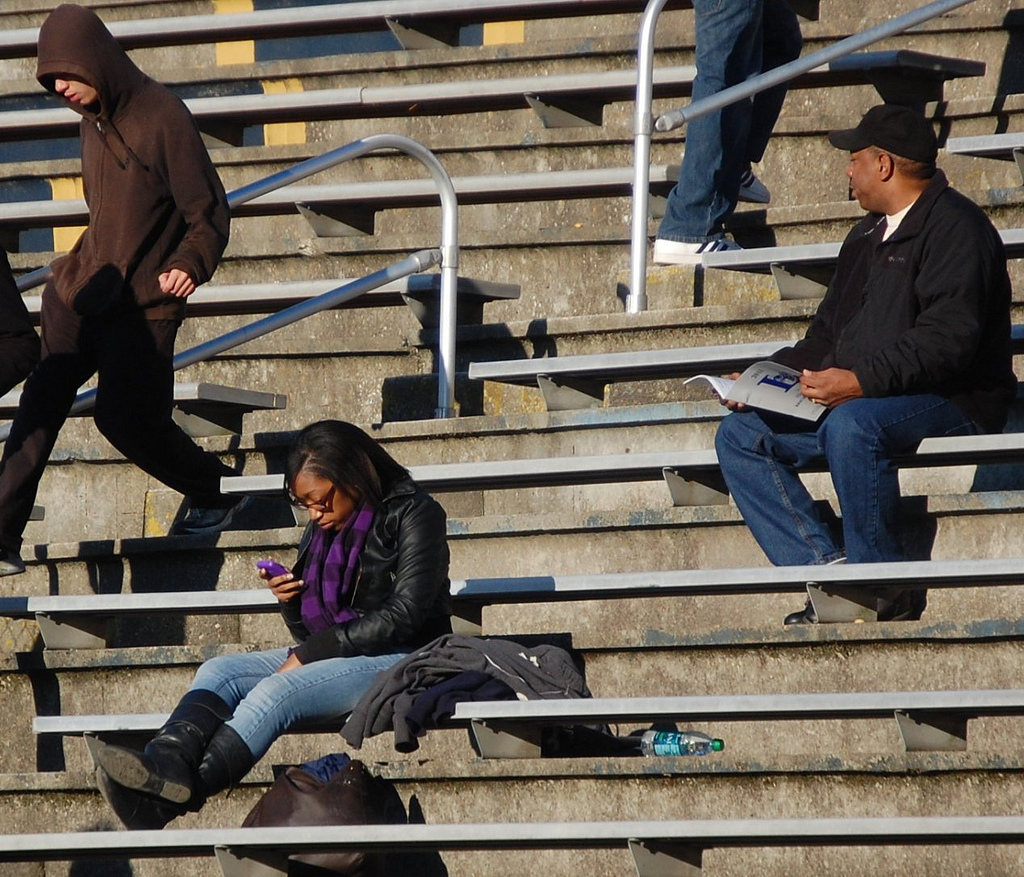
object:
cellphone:
[255, 559, 298, 586]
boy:
[715, 103, 1014, 618]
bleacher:
[726, 696, 800, 753]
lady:
[85, 418, 454, 813]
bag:
[235, 752, 422, 877]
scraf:
[296, 510, 372, 637]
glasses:
[290, 483, 337, 510]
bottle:
[641, 730, 726, 757]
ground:
[611, 649, 649, 698]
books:
[681, 359, 832, 424]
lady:
[0, 0, 250, 586]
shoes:
[655, 227, 757, 269]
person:
[654, 0, 821, 264]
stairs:
[769, 80, 829, 207]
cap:
[829, 104, 939, 165]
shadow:
[380, 273, 556, 425]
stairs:
[520, 50, 605, 128]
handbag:
[466, 716, 540, 761]